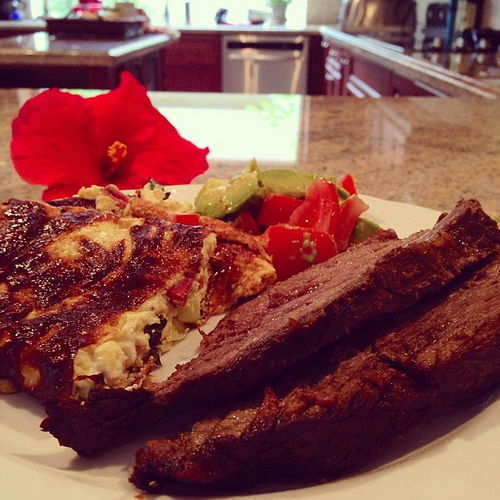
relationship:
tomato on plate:
[252, 183, 347, 278] [2, 184, 494, 495]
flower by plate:
[10, 67, 206, 189] [8, 163, 473, 359]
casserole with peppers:
[21, 213, 192, 311] [97, 120, 361, 237]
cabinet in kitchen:
[162, 30, 223, 92] [4, 8, 468, 498]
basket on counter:
[52, 16, 161, 46] [16, 21, 163, 63]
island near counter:
[11, 10, 176, 69] [2, 0, 305, 31]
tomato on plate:
[232, 207, 263, 238] [2, 184, 494, 495]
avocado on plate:
[191, 156, 353, 220] [2, 184, 494, 495]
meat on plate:
[128, 248, 500, 498] [2, 184, 494, 495]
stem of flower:
[101, 139, 128, 177] [10, 69, 210, 202]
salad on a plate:
[131, 158, 402, 263] [2, 184, 494, 495]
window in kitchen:
[153, 2, 305, 36] [0, 0, 497, 196]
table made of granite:
[27, 130, 490, 497] [29, 66, 484, 218]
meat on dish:
[128, 181, 478, 422] [2, 160, 477, 490]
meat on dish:
[128, 248, 500, 498] [21, 171, 484, 498]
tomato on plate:
[232, 207, 263, 238] [253, 173, 422, 270]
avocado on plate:
[275, 164, 307, 192] [150, 170, 371, 242]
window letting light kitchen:
[186, 0, 311, 38] [4, 8, 468, 498]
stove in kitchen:
[220, 24, 308, 93] [4, 8, 468, 498]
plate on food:
[2, 184, 494, 495] [6, 169, 473, 479]